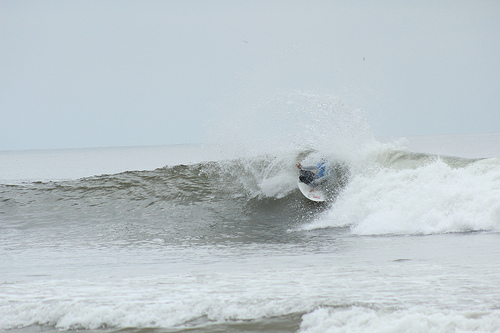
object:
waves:
[0, 150, 500, 236]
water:
[10, 137, 498, 331]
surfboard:
[297, 181, 327, 202]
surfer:
[299, 157, 327, 191]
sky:
[0, 1, 498, 121]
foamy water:
[6, 258, 497, 332]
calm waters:
[7, 145, 161, 178]